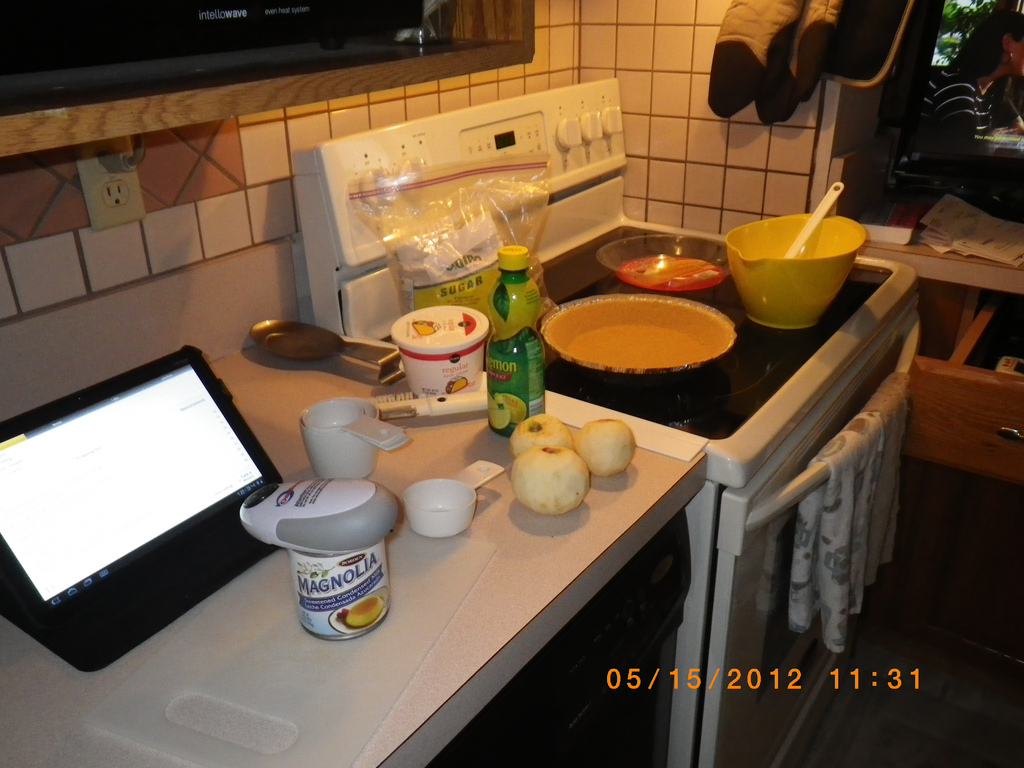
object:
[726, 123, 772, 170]
tile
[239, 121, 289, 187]
tile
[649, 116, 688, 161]
tile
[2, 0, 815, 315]
wall